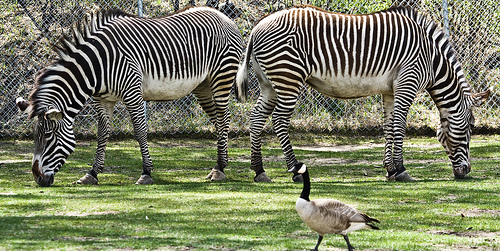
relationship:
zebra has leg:
[234, 7, 486, 192] [250, 95, 273, 190]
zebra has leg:
[234, 7, 486, 192] [270, 93, 309, 189]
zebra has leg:
[234, 7, 486, 192] [375, 100, 397, 187]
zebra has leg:
[234, 7, 486, 192] [392, 85, 413, 181]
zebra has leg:
[14, 2, 247, 193] [79, 104, 111, 199]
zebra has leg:
[14, 2, 247, 193] [124, 104, 173, 188]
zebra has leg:
[14, 2, 247, 193] [187, 79, 234, 129]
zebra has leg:
[14, 2, 247, 193] [209, 70, 235, 182]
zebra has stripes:
[14, 2, 247, 193] [142, 30, 206, 73]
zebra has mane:
[234, 7, 486, 192] [409, 5, 486, 118]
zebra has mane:
[14, 2, 247, 193] [45, 4, 149, 60]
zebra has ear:
[14, 2, 247, 193] [13, 88, 39, 132]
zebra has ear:
[14, 2, 247, 193] [42, 94, 67, 132]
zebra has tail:
[234, 7, 486, 192] [232, 34, 255, 108]